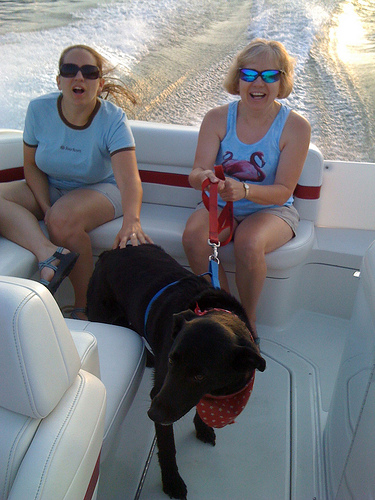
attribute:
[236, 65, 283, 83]
sunglasses — blue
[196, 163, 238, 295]
leach — blue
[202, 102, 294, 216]
shirt — gray 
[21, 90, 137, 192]
shirt — blue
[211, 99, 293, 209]
shirt — blue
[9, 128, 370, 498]
cushions — white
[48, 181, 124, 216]
shorts — khaki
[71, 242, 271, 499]
dog — black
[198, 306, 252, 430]
bandana — red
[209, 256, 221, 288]
leash — blue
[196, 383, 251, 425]
dots — white